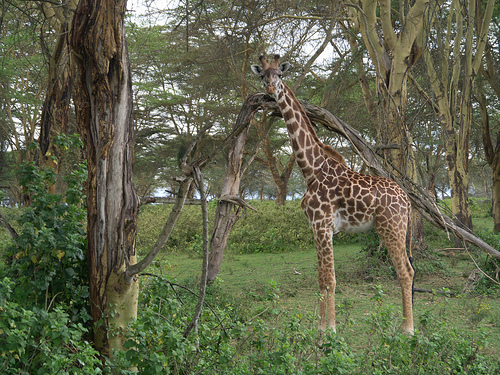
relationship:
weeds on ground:
[159, 266, 347, 366] [49, 287, 492, 370]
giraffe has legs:
[251, 59, 430, 319] [312, 232, 425, 353]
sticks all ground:
[203, 302, 284, 340] [49, 287, 492, 370]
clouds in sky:
[297, 43, 333, 64] [113, 10, 455, 108]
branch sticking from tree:
[183, 158, 220, 321] [41, 8, 229, 311]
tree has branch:
[41, 8, 229, 311] [137, 182, 263, 220]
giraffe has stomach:
[251, 59, 430, 319] [330, 216, 377, 236]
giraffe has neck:
[251, 59, 430, 319] [275, 89, 320, 169]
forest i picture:
[42, 25, 494, 199] [30, 44, 499, 346]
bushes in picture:
[110, 186, 303, 251] [30, 44, 499, 346]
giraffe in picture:
[251, 55, 419, 334] [30, 44, 499, 346]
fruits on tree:
[53, 245, 78, 267] [41, 8, 229, 311]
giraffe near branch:
[251, 55, 419, 334] [183, 158, 220, 321]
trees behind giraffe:
[191, 14, 477, 183] [251, 59, 430, 319]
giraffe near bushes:
[251, 55, 419, 334] [110, 186, 303, 251]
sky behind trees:
[113, 10, 455, 108] [59, 6, 256, 343]